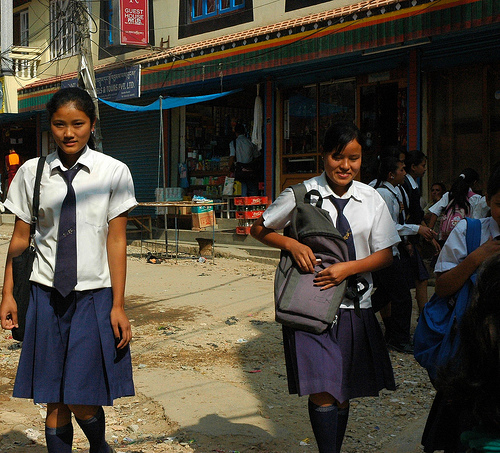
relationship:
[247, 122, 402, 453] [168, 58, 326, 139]
girl in front of building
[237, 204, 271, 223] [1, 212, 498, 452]
soda rack on ground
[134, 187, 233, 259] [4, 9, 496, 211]
table in front of store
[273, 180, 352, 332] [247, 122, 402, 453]
backpack on girl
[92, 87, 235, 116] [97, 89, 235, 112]
tarp for tarp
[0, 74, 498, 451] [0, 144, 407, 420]
children wearing uniforms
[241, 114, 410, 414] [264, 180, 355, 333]
girl holding backpack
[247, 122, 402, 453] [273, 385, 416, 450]
girl wearing socks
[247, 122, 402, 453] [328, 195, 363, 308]
girl wearing tie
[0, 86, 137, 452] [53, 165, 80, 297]
children wearing tie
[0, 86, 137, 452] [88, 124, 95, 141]
children wearing earring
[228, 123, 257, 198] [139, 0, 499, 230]
person in store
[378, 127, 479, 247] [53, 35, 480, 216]
kids by building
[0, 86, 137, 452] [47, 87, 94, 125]
children has hair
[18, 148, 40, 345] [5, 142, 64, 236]
bag around shoulder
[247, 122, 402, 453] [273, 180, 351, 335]
girl has backpack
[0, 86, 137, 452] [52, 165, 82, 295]
children wearing a tie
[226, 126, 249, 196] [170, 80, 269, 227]
person in store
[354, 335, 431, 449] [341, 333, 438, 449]
rocks and trash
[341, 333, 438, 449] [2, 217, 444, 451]
trash on ground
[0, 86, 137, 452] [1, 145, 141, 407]
children wearing a outfit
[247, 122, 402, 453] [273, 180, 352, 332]
girl putting something in backpack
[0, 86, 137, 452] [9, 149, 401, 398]
children walking in uniforms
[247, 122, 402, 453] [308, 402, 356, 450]
girl wearing socks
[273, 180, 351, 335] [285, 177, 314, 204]
backpack over shoulder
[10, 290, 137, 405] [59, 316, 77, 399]
skirt with pleat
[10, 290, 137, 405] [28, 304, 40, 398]
skirt with pleat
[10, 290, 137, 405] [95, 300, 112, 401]
skirt with pleat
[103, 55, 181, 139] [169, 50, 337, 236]
sign hanging above store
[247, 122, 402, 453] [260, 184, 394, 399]
girl wearing a outfit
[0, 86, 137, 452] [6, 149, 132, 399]
children wearing a outfit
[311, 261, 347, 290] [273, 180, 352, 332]
hand on backpack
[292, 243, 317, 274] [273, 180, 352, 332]
hands on backpack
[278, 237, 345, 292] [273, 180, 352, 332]
hands on backpack